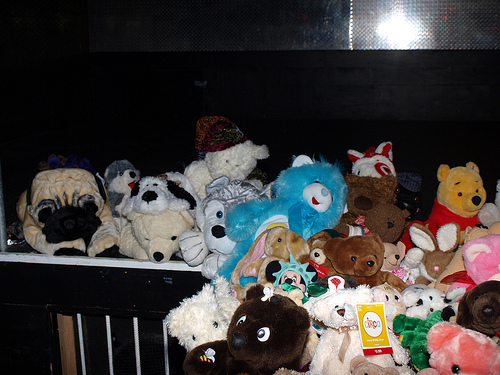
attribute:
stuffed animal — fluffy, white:
[404, 286, 466, 320]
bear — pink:
[413, 321, 483, 372]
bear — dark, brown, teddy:
[205, 284, 313, 368]